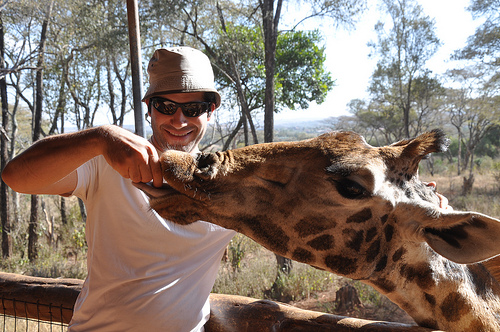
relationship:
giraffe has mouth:
[134, 124, 500, 330] [132, 163, 215, 227]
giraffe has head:
[134, 124, 500, 330] [130, 127, 499, 293]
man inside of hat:
[2, 45, 239, 329] [139, 44, 223, 113]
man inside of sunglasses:
[2, 45, 239, 329] [146, 93, 214, 122]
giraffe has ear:
[134, 124, 500, 330] [392, 199, 499, 267]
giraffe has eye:
[134, 124, 500, 330] [325, 167, 377, 209]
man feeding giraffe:
[2, 45, 239, 329] [134, 124, 500, 330]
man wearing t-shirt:
[2, 45, 239, 329] [59, 138, 240, 331]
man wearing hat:
[2, 45, 239, 329] [139, 44, 223, 113]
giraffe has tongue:
[134, 124, 500, 330] [129, 176, 178, 201]